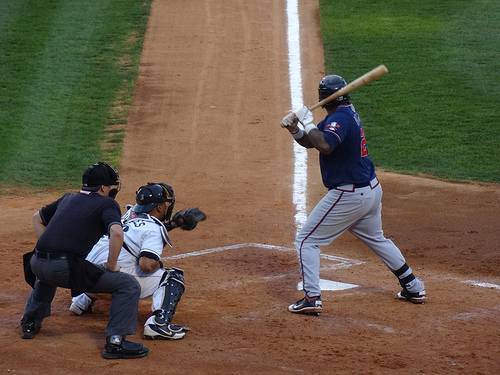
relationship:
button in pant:
[356, 189, 367, 201] [294, 181, 419, 298]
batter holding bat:
[279, 74, 426, 314] [343, 63, 389, 102]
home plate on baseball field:
[295, 276, 362, 294] [2, 1, 494, 258]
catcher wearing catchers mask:
[68, 182, 207, 341] [131, 182, 176, 219]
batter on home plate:
[282, 73, 427, 316] [295, 274, 357, 293]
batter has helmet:
[282, 73, 427, 316] [316, 73, 351, 105]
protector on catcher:
[151, 268, 186, 326] [68, 180, 208, 341]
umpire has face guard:
[15, 160, 149, 358] [75, 161, 122, 200]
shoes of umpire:
[102, 339, 147, 360] [15, 160, 149, 358]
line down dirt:
[274, 2, 321, 246] [153, 1, 488, 356]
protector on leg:
[154, 263, 199, 333] [130, 257, 210, 334]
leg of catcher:
[130, 257, 210, 334] [68, 180, 208, 341]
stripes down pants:
[297, 190, 342, 293] [292, 175, 426, 296]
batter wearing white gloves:
[279, 74, 426, 314] [294, 107, 317, 132]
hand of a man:
[103, 263, 123, 271] [15, 164, 142, 351]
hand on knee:
[103, 263, 123, 271] [111, 257, 138, 308]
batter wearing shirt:
[279, 74, 426, 314] [318, 104, 374, 191]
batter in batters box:
[279, 74, 426, 314] [136, 242, 496, 336]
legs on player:
[248, 166, 453, 318] [280, 63, 427, 313]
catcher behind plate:
[82, 183, 206, 339] [240, 241, 385, 316]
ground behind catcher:
[413, 139, 417, 148] [68, 180, 208, 341]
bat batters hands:
[278, 58, 395, 118] [280, 104, 314, 130]